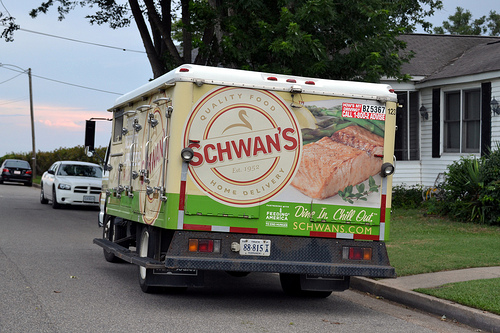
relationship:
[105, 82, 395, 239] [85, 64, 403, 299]
sign painted on truck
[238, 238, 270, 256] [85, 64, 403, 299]
license plate mounted on truck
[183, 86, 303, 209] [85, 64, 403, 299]
logo painted on truck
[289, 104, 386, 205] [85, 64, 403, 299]
picture painted on truck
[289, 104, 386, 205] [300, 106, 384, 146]
picture of asparagus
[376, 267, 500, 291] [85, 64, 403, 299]
sidewalk to right of truck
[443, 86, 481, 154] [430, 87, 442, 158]
window has shutter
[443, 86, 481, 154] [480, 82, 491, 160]
window has shutter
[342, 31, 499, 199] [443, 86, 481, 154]
house has window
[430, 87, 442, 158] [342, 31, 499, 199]
shutter mounted on house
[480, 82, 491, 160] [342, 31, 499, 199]
shutter mounted on house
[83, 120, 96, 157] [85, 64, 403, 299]
mirror mounted on truck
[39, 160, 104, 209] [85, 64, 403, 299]
car in front of truck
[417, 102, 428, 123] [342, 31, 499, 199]
lamp mounted on house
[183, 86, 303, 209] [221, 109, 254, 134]
logo includes swan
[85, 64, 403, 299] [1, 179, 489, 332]
truck parked on road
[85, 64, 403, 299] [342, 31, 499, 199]
truck parked in front of house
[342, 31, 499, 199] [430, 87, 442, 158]
house has shutter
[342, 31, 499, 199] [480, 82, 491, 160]
house has shutter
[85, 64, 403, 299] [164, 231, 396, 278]
truck has a bumper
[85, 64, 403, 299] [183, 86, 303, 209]
truck has logo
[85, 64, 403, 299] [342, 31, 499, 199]
truck in front of house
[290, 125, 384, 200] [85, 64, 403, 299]
salmon fillet painted on truck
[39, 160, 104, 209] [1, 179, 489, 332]
car parked on road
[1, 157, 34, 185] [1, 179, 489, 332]
car parked on road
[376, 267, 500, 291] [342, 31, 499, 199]
sidewalk in front of house